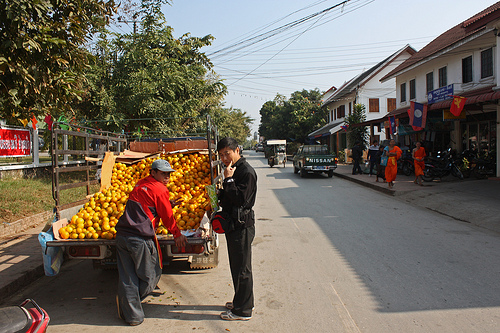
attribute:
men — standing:
[110, 132, 265, 325]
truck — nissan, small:
[41, 106, 224, 272]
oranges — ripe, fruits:
[69, 148, 206, 235]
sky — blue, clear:
[172, 2, 491, 105]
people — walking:
[352, 134, 431, 189]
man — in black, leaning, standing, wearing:
[111, 151, 187, 323]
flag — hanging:
[436, 90, 469, 118]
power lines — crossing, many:
[183, 5, 372, 81]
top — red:
[126, 174, 171, 202]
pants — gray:
[114, 233, 164, 318]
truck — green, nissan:
[289, 140, 341, 179]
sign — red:
[447, 93, 467, 120]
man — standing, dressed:
[207, 133, 261, 322]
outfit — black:
[210, 156, 263, 319]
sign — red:
[0, 123, 38, 161]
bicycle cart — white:
[263, 138, 289, 170]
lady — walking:
[379, 138, 399, 186]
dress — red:
[383, 146, 406, 183]